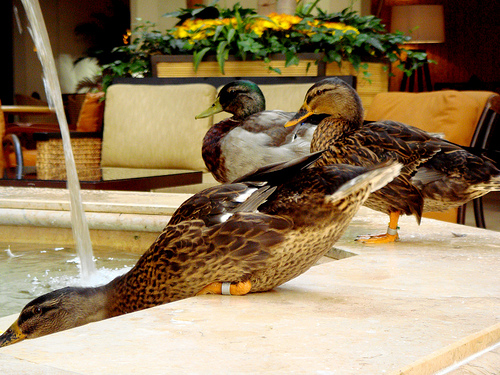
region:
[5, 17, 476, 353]
Ducks in the shot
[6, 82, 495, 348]
Brown ducks are female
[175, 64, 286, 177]
This is a male duck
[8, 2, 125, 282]
Water is running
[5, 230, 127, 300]
The water is clean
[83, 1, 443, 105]
Yellow flowers in the plant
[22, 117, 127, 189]
A brown basket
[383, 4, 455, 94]
A white lamp in the background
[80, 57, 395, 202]
The sofa is white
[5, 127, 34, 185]
A steel stand for the table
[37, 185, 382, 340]
duck is getting in the water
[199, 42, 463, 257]
the ducks are standing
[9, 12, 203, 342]
waterfall into a fountain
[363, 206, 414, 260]
duck has orange feet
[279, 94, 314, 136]
duck has orange beak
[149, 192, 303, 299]
duck has brown feathers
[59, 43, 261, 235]
chairs next to the ducks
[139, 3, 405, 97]
flowers above the chairs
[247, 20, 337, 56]
the leaves are green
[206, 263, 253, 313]
rubber band on the duck's foot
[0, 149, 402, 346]
duck is leaning into indoor fountain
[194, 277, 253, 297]
leaning duck has silver band on leg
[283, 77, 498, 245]
brown and yellow standing duck next to fountain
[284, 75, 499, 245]
standing brown duck has tag on leg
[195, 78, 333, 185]
duck with green head standing by fountain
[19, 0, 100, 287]
indoor fountain has strong spray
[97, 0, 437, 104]
greenery arrangement in long wooden planter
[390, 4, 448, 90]
table lamp in corner has beige lampshade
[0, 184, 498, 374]
ledge of fountain is made of marble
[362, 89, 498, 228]
chair with golden yellow upholstery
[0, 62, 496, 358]
three ducks on edge of swimming pool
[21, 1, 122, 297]
a stream of water flows into the swimming pool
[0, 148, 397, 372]
a duck is drinking water from swimming pool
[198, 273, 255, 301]
leg of duck is orange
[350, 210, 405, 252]
legs of duck are orange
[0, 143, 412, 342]
duck is color brown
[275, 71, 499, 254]
duck is color brown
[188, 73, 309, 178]
duck is color brown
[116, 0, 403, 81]
yellow flowers on large pot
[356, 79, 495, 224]
a chair behind a duck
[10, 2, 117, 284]
water filling the pond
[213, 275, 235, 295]
strap on duck foot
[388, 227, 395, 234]
strap on duck foot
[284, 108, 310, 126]
beak on the duck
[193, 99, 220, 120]
beak on the duck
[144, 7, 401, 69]
plant on the shelf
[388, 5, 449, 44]
shade on the lamp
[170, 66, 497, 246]
ducks standing on the ledge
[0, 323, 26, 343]
beak on the duck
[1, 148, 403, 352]
duck laying on the ledge